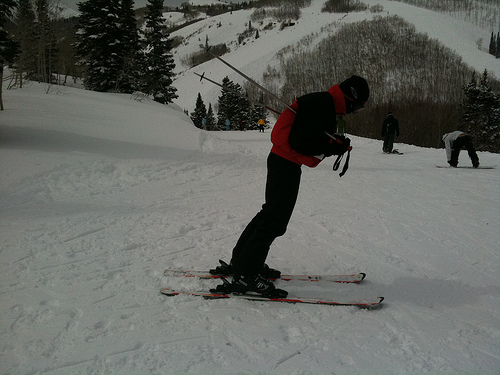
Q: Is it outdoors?
A: Yes, it is outdoors.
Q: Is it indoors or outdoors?
A: It is outdoors.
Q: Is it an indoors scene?
A: No, it is outdoors.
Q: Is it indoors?
A: No, it is outdoors.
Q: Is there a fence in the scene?
A: No, there are no fences.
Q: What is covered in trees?
A: The mountain is covered in trees.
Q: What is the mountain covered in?
A: The mountain is covered in trees.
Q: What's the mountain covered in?
A: The mountain is covered in trees.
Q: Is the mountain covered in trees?
A: Yes, the mountain is covered in trees.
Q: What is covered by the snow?
A: The mountain is covered by the snow.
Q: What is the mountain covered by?
A: The mountain is covered by the snow.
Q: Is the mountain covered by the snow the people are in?
A: Yes, the mountain is covered by the snow.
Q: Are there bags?
A: No, there are no bags.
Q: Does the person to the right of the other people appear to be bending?
A: Yes, the person is bending.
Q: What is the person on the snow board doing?
A: The person is bending.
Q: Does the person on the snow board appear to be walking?
A: No, the person is bending.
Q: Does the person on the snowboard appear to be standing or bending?
A: The person is bending.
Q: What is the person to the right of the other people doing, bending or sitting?
A: The person is bending.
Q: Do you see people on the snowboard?
A: Yes, there is a person on the snowboard.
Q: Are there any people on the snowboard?
A: Yes, there is a person on the snowboard.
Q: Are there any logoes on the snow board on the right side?
A: No, there is a person on the snow board.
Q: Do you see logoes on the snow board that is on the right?
A: No, there is a person on the snow board.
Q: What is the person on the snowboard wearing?
A: The person is wearing pants.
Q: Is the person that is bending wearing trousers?
A: Yes, the person is wearing trousers.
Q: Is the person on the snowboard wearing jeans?
A: No, the person is wearing trousers.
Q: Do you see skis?
A: Yes, there are skis.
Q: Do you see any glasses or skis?
A: Yes, there are skis.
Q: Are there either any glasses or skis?
A: Yes, there are skis.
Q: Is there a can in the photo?
A: No, there are no cans.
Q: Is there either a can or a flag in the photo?
A: No, there are no cans or flags.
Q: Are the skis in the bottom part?
A: Yes, the skis are in the bottom of the image.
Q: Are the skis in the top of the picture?
A: No, the skis are in the bottom of the image.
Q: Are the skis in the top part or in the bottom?
A: The skis are in the bottom of the image.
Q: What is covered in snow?
A: The skis are covered in snow.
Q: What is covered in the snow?
A: The skis are covered in snow.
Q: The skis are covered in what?
A: The skis are covered in snow.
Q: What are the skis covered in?
A: The skis are covered in snow.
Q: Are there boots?
A: Yes, there are boots.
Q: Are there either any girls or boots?
A: Yes, there are boots.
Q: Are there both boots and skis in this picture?
A: Yes, there are both boots and skis.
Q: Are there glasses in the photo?
A: No, there are no glasses.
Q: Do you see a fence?
A: No, there are no fences.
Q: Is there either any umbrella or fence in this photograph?
A: No, there are no fences or umbrellas.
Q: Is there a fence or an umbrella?
A: No, there are no fences or umbrellas.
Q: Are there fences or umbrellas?
A: No, there are no fences or umbrellas.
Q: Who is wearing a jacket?
A: The people are wearing a jacket.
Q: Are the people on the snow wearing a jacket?
A: Yes, the people are wearing a jacket.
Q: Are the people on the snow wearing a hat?
A: No, the people are wearing a jacket.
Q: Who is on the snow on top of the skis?
A: The people are on the snow.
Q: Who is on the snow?
A: The people are on the snow.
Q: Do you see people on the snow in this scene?
A: Yes, there are people on the snow.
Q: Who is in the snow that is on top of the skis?
A: The people are in the snow.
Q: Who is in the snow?
A: The people are in the snow.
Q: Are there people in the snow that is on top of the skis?
A: Yes, there are people in the snow.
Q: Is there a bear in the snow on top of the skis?
A: No, there are people in the snow.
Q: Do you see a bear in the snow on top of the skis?
A: No, there are people in the snow.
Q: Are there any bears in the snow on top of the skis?
A: No, there are people in the snow.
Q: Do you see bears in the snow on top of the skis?
A: No, there are people in the snow.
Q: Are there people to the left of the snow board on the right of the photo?
A: Yes, there are people to the left of the snowboard.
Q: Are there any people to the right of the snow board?
A: No, the people are to the left of the snow board.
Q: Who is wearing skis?
A: The people are wearing skis.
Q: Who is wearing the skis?
A: The people are wearing skis.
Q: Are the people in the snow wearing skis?
A: Yes, the people are wearing skis.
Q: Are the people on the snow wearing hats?
A: No, the people are wearing skis.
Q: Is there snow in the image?
A: Yes, there is snow.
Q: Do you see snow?
A: Yes, there is snow.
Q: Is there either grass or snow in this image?
A: Yes, there is snow.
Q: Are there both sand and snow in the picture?
A: No, there is snow but no sand.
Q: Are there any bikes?
A: No, there are no bikes.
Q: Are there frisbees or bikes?
A: No, there are no bikes or frisbees.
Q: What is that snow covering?
A: The snow is covering the mountain.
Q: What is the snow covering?
A: The snow is covering the mountain.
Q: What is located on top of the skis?
A: The snow is on top of the skis.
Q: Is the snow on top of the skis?
A: Yes, the snow is on top of the skis.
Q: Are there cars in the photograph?
A: No, there are no cars.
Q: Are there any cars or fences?
A: No, there are no cars or fences.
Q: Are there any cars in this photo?
A: No, there are no cars.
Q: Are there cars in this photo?
A: No, there are no cars.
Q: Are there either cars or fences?
A: No, there are no cars or fences.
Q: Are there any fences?
A: No, there are no fences.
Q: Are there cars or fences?
A: No, there are no fences or cars.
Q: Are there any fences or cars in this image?
A: No, there are no fences or cars.